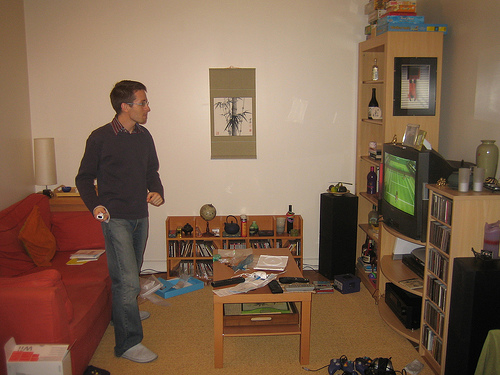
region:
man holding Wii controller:
[85, 195, 117, 233]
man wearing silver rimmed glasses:
[102, 72, 162, 134]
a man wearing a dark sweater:
[68, 113, 169, 230]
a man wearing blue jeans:
[94, 205, 154, 353]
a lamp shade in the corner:
[26, 126, 66, 197]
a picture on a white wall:
[204, 58, 263, 166]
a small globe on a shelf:
[197, 200, 223, 241]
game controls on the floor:
[318, 346, 404, 373]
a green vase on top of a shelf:
[468, 133, 498, 195]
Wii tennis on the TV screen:
[375, 147, 425, 226]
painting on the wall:
[196, 25, 266, 168]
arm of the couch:
[3, 271, 80, 325]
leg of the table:
[205, 297, 225, 371]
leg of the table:
[296, 307, 318, 363]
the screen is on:
[382, 157, 417, 212]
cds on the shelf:
[421, 190, 456, 223]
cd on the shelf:
[422, 227, 467, 252]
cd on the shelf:
[430, 245, 454, 278]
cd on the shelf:
[429, 278, 453, 303]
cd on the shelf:
[425, 303, 452, 338]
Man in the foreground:
[61, 61, 191, 370]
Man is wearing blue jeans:
[93, 207, 168, 364]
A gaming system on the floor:
[325, 263, 370, 302]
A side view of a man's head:
[101, 71, 162, 140]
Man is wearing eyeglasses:
[105, 72, 162, 135]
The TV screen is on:
[368, 129, 432, 241]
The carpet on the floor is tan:
[86, 252, 441, 374]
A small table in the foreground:
[201, 235, 317, 372]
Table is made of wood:
[191, 235, 327, 371]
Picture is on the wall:
[206, 92, 260, 146]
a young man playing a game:
[73, 80, 163, 365]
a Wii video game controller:
[95, 212, 103, 219]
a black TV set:
[377, 140, 476, 242]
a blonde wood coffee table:
[211, 246, 313, 366]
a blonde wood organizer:
[163, 213, 304, 277]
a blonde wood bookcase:
[357, 30, 439, 297]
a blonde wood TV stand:
[376, 220, 426, 348]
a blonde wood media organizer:
[417, 181, 499, 373]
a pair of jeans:
[101, 219, 148, 356]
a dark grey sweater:
[72, 120, 164, 219]